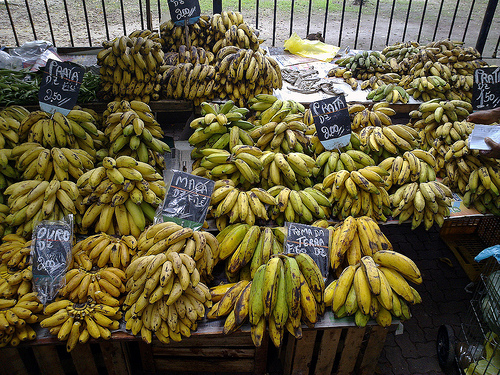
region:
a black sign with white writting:
[301, 91, 363, 161]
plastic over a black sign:
[25, 216, 81, 311]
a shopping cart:
[434, 251, 498, 373]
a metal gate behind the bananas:
[0, 0, 498, 50]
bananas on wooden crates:
[0, 277, 412, 372]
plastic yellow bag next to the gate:
[282, 28, 350, 71]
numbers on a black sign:
[317, 122, 347, 141]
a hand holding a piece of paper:
[458, 93, 496, 155]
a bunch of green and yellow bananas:
[92, 94, 174, 168]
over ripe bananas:
[210, 277, 259, 333]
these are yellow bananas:
[31, 94, 408, 328]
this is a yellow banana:
[354, 252, 399, 305]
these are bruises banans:
[281, 282, 312, 314]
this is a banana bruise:
[156, 268, 171, 280]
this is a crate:
[263, 248, 401, 373]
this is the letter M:
[175, 175, 188, 189]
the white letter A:
[185, 177, 197, 192]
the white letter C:
[194, 180, 203, 196]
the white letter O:
[59, 229, 71, 244]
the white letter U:
[43, 227, 58, 240]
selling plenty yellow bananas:
[71, 65, 375, 310]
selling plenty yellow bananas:
[131, 172, 361, 356]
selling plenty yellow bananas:
[182, 91, 352, 335]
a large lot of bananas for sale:
[13, 13, 471, 328]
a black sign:
[29, 220, 66, 285]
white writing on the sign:
[174, 180, 205, 217]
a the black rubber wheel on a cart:
[434, 324, 456, 370]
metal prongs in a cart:
[469, 282, 496, 342]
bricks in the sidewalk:
[418, 258, 454, 309]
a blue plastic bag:
[475, 245, 492, 260]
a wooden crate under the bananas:
[284, 331, 402, 373]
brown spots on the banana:
[160, 262, 173, 282]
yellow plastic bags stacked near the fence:
[289, 32, 336, 58]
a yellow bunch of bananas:
[326, 249, 427, 333]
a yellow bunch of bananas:
[242, 253, 319, 348]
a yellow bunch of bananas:
[331, 219, 386, 264]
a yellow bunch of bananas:
[210, 227, 278, 274]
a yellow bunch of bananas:
[118, 256, 198, 309]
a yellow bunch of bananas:
[136, 220, 213, 265]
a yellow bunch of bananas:
[207, 180, 267, 227]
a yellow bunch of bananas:
[271, 182, 321, 220]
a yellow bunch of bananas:
[322, 163, 387, 214]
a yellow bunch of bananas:
[385, 183, 457, 225]